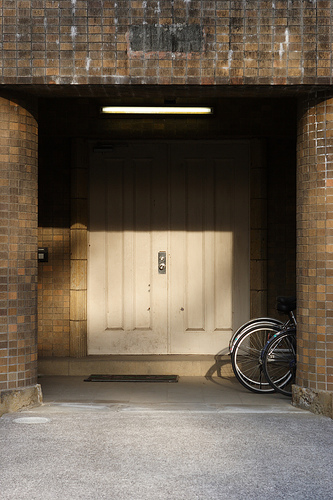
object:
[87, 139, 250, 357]
door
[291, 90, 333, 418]
pillar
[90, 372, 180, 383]
doormat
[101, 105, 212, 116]
light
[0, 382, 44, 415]
base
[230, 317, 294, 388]
wheel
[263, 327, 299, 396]
wheel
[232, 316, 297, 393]
wheel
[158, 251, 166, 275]
doorknob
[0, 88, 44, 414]
pillar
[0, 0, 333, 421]
building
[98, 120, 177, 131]
object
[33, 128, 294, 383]
wall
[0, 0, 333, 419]
house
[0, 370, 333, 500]
ground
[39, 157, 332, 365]
section